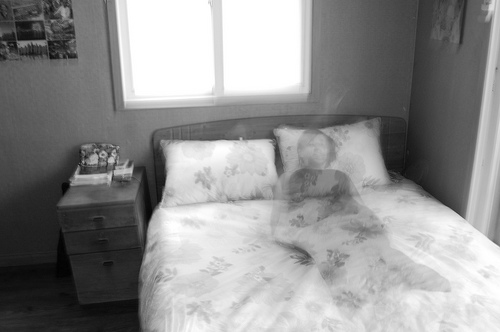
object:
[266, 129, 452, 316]
figure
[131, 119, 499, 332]
bed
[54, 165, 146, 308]
nightstand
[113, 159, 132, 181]
items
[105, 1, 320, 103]
window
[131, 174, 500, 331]
sheets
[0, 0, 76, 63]
pictures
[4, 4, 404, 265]
wall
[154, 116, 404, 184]
headboard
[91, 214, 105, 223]
pulls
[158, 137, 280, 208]
left pillow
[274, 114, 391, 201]
right pillow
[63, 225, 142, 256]
drawers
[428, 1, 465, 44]
artwork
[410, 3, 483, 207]
wall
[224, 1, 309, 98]
right pane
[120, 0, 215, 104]
left pane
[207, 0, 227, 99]
divider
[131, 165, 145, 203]
edge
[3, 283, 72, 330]
floor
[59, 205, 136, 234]
drawer